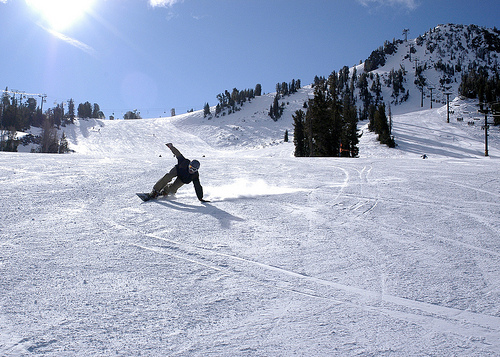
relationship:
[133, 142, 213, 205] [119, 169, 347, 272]
man on slope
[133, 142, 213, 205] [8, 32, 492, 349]
man falling in snow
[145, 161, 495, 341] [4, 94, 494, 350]
ski marks in snow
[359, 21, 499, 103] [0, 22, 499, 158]
trees on hill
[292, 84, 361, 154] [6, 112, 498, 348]
trees on ground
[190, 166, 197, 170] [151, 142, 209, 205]
goggles on person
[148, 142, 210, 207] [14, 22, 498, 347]
man on hill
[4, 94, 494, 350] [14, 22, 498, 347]
snow on hill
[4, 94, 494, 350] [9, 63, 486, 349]
snow on hill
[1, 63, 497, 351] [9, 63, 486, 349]
snow on hill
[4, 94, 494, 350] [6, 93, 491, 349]
snow on hill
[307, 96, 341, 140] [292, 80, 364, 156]
leaves on tree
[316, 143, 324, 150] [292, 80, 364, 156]
leaves on tree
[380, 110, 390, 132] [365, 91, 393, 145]
leaves on tree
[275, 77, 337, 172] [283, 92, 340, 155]
leaves on tree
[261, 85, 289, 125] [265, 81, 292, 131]
leaves on tree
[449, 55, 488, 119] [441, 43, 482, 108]
leaves on tree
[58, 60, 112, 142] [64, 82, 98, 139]
leaves on tree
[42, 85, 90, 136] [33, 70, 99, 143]
leaves on tree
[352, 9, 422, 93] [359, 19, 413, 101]
leaves on tree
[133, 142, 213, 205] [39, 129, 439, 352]
man on snow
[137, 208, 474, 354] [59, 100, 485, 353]
tracks in snow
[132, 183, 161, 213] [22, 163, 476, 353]
snowboard on snow